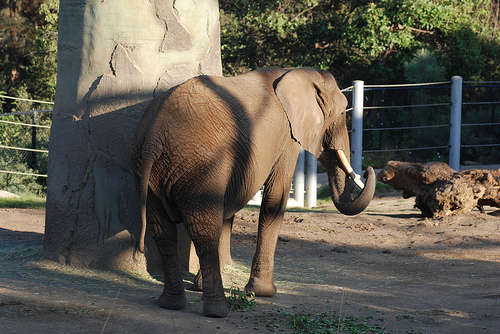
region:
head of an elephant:
[263, 51, 381, 166]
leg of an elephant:
[150, 218, 197, 326]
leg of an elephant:
[180, 188, 218, 323]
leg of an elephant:
[240, 193, 314, 285]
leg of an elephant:
[193, 183, 247, 287]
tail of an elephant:
[90, 156, 164, 276]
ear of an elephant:
[250, 21, 374, 158]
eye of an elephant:
[315, 79, 379, 134]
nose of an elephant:
[339, 163, 387, 225]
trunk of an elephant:
[332, 143, 387, 198]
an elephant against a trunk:
[44, 3, 435, 300]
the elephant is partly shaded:
[125, 47, 390, 309]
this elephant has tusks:
[324, 135, 371, 193]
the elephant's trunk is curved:
[313, 122, 407, 214]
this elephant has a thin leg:
[253, 153, 295, 299]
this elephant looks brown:
[123, 45, 375, 252]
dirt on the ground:
[308, 220, 484, 322]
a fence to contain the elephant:
[350, 62, 492, 217]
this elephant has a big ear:
[258, 62, 338, 171]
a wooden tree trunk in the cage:
[381, 142, 498, 231]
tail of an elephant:
[117, 171, 175, 278]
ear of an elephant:
[249, 59, 334, 170]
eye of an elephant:
[337, 105, 359, 123]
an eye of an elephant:
[332, 102, 360, 123]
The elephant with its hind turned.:
[140, 60, 366, 330]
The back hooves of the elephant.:
[150, 277, 227, 327]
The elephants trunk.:
[327, 143, 377, 222]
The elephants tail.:
[130, 135, 154, 275]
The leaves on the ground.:
[256, 303, 383, 332]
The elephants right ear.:
[272, 68, 329, 167]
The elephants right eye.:
[334, 104, 343, 119]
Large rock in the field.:
[390, 158, 497, 209]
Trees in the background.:
[320, 5, 492, 56]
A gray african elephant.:
[128, 66, 376, 318]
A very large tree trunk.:
[41, 0, 223, 272]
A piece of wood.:
[378, 158, 499, 220]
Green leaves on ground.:
[217, 286, 417, 332]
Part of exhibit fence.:
[342, 76, 499, 178]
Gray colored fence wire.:
[0, 93, 55, 177]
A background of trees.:
[219, 0, 499, 82]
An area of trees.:
[0, 0, 60, 102]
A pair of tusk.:
[335, 149, 365, 188]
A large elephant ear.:
[273, 65, 326, 160]